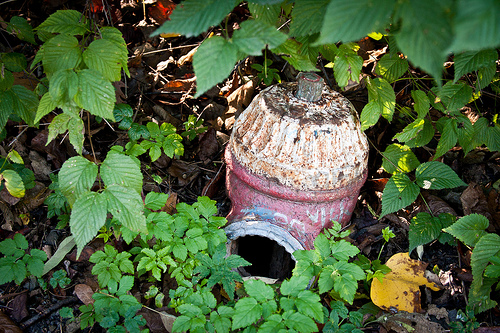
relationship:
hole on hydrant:
[231, 233, 296, 285] [224, 75, 370, 286]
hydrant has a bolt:
[224, 75, 370, 286] [296, 66, 325, 102]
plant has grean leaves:
[0, 0, 149, 328] [69, 190, 109, 264]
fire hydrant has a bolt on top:
[224, 75, 370, 286] [296, 66, 325, 102]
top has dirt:
[225, 70, 369, 187] [262, 83, 353, 123]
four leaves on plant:
[57, 146, 147, 258] [0, 0, 149, 328]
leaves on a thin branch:
[378, 141, 464, 253] [371, 137, 443, 231]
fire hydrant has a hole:
[224, 75, 370, 286] [231, 233, 296, 285]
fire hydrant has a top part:
[224, 75, 370, 286] [225, 70, 369, 187]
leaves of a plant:
[378, 141, 464, 253] [0, 0, 149, 328]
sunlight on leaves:
[369, 0, 498, 210] [367, 0, 498, 331]